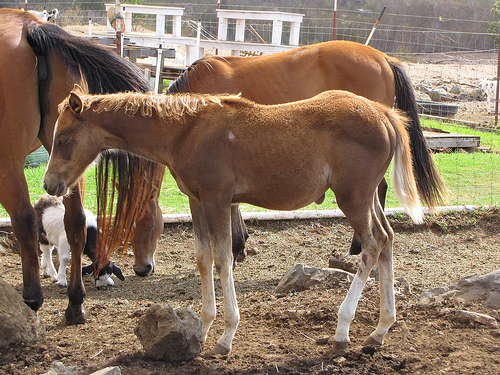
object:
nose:
[131, 263, 152, 277]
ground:
[0, 48, 500, 370]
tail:
[384, 105, 430, 228]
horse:
[38, 80, 433, 362]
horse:
[0, 2, 171, 330]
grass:
[0, 76, 500, 221]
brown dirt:
[0, 202, 500, 375]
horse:
[107, 36, 460, 280]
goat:
[32, 189, 127, 291]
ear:
[67, 90, 84, 117]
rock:
[130, 298, 210, 364]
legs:
[328, 181, 391, 355]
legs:
[199, 185, 241, 358]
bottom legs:
[191, 252, 218, 348]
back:
[202, 90, 322, 117]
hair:
[53, 88, 245, 126]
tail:
[382, 58, 459, 220]